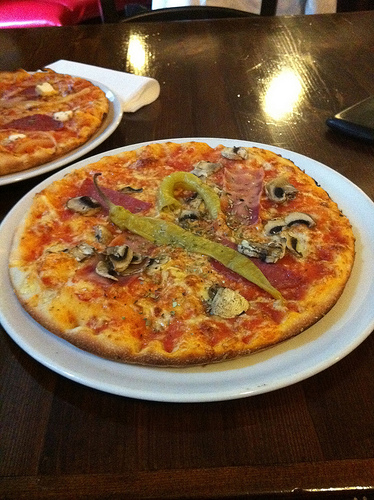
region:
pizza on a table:
[2, 16, 373, 488]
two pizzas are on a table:
[0, 57, 373, 416]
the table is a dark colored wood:
[1, 9, 372, 497]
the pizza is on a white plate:
[3, 133, 373, 400]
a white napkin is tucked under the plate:
[38, 51, 161, 124]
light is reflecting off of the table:
[120, 15, 332, 135]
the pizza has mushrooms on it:
[9, 128, 348, 386]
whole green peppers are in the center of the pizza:
[76, 164, 292, 317]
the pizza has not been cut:
[13, 136, 362, 377]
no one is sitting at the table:
[85, 0, 300, 29]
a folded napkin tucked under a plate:
[47, 51, 156, 112]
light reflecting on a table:
[261, 62, 308, 121]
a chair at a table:
[97, 0, 279, 22]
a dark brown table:
[1, 10, 372, 496]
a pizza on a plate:
[7, 139, 355, 367]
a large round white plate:
[7, 138, 370, 402]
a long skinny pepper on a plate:
[91, 172, 282, 298]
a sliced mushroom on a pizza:
[269, 208, 312, 239]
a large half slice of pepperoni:
[209, 232, 308, 290]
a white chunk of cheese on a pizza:
[34, 80, 56, 95]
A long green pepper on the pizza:
[95, 196, 278, 293]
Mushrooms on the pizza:
[83, 247, 157, 282]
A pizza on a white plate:
[14, 145, 358, 416]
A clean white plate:
[50, 355, 194, 399]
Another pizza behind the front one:
[0, 76, 126, 174]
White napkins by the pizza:
[59, 54, 176, 105]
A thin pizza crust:
[90, 325, 267, 363]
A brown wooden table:
[177, 55, 302, 122]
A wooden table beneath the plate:
[68, 420, 298, 470]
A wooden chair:
[101, 0, 281, 32]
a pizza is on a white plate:
[3, 133, 373, 401]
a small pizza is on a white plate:
[0, 65, 122, 187]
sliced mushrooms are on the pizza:
[263, 168, 322, 268]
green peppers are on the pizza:
[101, 167, 282, 312]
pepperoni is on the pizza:
[212, 159, 261, 219]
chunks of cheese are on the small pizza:
[2, 78, 70, 135]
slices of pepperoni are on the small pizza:
[6, 80, 61, 140]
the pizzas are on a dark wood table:
[6, 11, 373, 488]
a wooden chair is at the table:
[96, 2, 281, 23]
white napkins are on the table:
[43, 56, 163, 115]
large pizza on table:
[31, 136, 357, 350]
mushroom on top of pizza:
[207, 282, 257, 324]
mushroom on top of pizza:
[108, 246, 137, 265]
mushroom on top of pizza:
[234, 238, 282, 267]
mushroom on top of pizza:
[278, 228, 300, 259]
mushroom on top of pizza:
[269, 179, 294, 205]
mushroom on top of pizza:
[222, 143, 247, 161]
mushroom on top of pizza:
[63, 188, 95, 215]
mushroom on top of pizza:
[179, 205, 203, 226]